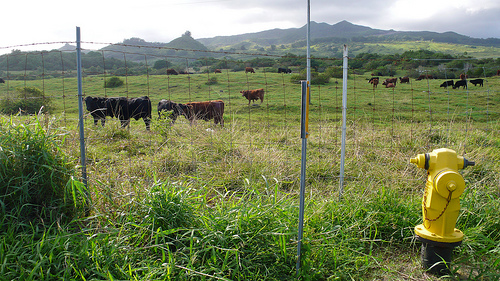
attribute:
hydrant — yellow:
[409, 142, 468, 249]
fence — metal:
[80, 36, 371, 222]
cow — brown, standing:
[235, 84, 264, 107]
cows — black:
[79, 88, 159, 142]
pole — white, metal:
[322, 49, 353, 196]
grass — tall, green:
[41, 134, 390, 278]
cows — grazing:
[108, 69, 494, 121]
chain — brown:
[422, 185, 456, 219]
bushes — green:
[2, 133, 82, 236]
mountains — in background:
[198, 26, 499, 56]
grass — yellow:
[257, 107, 498, 206]